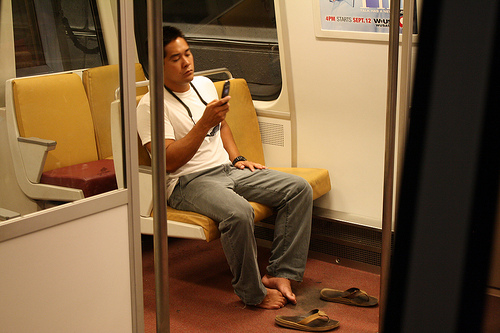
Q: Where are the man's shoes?
A: On the floor.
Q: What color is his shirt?
A: White.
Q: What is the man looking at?
A: His phone.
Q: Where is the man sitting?
A: Public transportation.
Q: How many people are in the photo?
A: One.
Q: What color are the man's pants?
A: Gray.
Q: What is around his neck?
A: Sunglasses.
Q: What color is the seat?
A: Yellow.